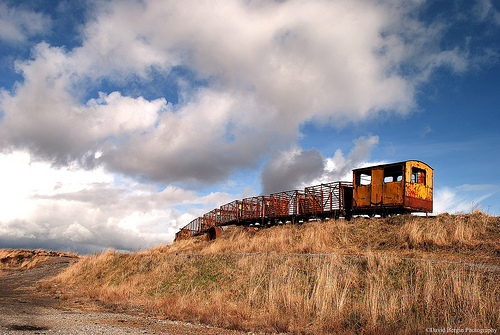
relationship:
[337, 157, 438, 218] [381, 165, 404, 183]
train car has window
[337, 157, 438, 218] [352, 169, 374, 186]
train car has window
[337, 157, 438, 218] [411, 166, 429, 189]
train car has window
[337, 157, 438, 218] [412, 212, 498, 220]
train car on tracks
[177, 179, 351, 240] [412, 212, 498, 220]
train cars on tracks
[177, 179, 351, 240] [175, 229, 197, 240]
train cars have wood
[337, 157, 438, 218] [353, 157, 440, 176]
train car has roof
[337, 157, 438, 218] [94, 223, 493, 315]
train car on hill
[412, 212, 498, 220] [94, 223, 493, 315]
tracks on hill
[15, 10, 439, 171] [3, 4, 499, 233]
cloud in sky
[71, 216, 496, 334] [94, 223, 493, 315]
field on hill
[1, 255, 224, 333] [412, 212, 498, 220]
road beside tracks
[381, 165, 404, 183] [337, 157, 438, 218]
window in train car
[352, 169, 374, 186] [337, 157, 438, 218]
window in train car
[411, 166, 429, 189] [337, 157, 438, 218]
window in train car